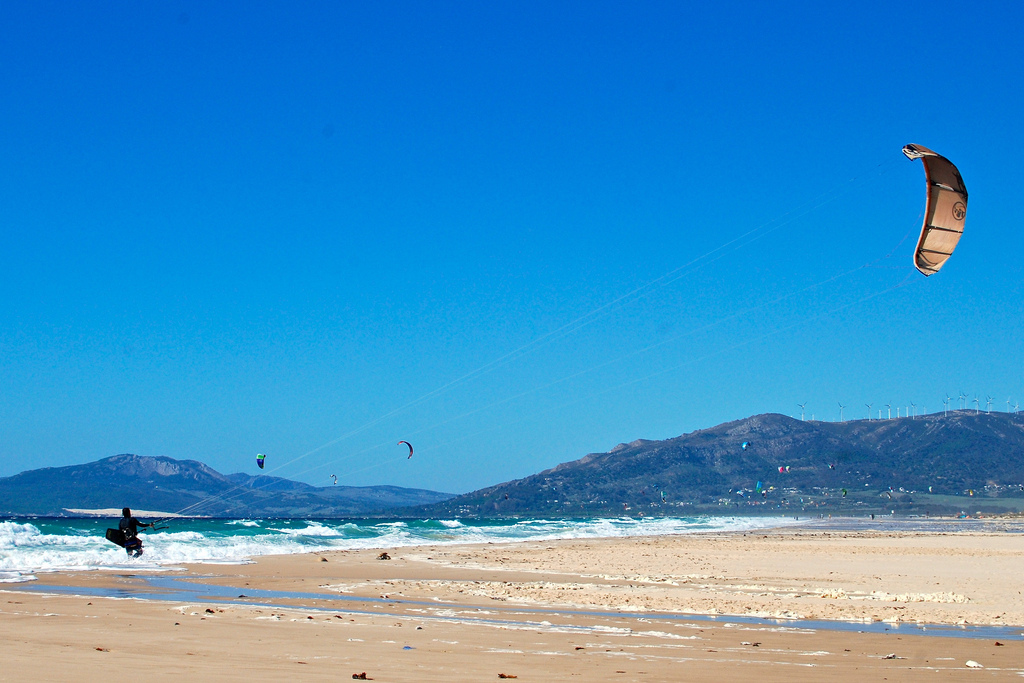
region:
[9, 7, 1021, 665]
a scene during the day time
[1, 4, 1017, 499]
a clear sky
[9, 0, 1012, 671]
a scene outside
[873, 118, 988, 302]
a kite in the air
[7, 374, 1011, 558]
hills in the background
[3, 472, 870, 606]
the ocean is here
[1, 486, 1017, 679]
a sandy shoreline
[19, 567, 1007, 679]
a water trail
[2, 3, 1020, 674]
the scene takes place outdoors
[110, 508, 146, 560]
the person is on the beach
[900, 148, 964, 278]
the person flies a kite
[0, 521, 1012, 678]
the sand is brown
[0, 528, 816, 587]
the waves are crashing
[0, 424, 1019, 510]
the hills are tall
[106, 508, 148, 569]
the man wears black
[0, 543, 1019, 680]
the sand has rocks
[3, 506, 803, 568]
the water is greenish blue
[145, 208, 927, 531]
the man holds a string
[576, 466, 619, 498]
green leaves on the tree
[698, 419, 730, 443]
green grass on the mountain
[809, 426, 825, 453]
green grass on the mountain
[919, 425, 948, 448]
green grass on the mountain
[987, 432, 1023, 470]
green grass on the mountain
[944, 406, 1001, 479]
green grass on the mountain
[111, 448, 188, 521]
green grass on the mountain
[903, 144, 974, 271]
large brown wide kite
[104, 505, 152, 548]
person walking on beach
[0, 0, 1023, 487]
large wide open blue sky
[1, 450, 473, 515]
large wide rugged mountains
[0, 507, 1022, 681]
large wide open beach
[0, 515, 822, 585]
large white green water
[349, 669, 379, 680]
black piece of sea weed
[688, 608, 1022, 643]
stream of blue water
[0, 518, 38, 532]
white small crashing wave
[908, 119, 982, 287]
large brown kite in blue sky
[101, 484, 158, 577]
surfer walking in ocean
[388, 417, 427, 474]
kite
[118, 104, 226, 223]
blue sky with no clouds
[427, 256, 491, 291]
blue sky with no clouds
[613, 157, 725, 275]
blue sky with no clouds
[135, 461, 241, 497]
mountain by tan beach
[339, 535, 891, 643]
a sandy beach near the ocean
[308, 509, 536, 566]
white waves in the water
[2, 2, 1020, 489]
clear blue daytime sky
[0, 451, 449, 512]
hazy mountains on horizon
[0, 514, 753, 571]
crashing waves on ocean edge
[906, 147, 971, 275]
underside of airborn parasail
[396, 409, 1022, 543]
mountain overlooking ocean beach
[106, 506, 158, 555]
man with parasail board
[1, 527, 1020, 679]
tan sand of ocean shoreline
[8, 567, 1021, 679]
small river in sand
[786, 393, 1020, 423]
row of wind turbines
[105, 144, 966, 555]
parasail tethered from white cables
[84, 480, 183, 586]
A man in the water.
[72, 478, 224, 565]
A man parachuting in the water.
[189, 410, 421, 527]
Wires from the kite.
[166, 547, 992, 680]
Sand on the ground.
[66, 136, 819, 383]
The sky is blue.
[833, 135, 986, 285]
A kite in the sky from the man.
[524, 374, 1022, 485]
Hills in the background.